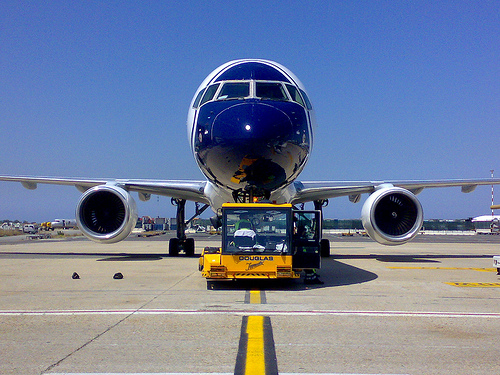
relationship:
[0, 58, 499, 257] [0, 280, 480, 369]
jet on tarmac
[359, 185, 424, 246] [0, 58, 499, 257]
engine on jet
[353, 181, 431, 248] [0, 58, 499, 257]
engine on jet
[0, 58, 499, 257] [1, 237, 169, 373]
jet on tarmac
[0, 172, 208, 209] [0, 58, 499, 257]
wing on jet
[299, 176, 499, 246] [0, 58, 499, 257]
wing on jet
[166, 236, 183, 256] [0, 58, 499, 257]
wheel on jet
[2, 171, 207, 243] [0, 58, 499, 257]
wing on jet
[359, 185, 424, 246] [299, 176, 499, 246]
engine on wing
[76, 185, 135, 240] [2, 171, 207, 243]
engine on wing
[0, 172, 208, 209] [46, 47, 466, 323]
wing on plane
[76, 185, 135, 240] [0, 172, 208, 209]
engine on wing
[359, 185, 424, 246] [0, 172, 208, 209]
engine on wing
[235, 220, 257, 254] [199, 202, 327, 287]
person on vehicle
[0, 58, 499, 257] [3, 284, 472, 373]
jet on tarmac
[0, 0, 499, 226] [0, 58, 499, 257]
sky above jet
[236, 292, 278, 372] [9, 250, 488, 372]
markings on a field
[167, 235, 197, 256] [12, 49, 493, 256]
rear-landing wheels of an airplane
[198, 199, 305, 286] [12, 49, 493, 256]
vehicle pulling an airplane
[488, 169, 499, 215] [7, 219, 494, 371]
radio antennae on an airplane field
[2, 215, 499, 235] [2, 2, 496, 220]
horizon connecting sky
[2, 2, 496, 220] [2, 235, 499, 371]
sky with an airplane field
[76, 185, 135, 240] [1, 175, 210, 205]
engine on wing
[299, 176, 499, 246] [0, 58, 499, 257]
wing of jet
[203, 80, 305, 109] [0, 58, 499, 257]
windshield on jet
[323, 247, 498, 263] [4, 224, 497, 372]
shadow on concrete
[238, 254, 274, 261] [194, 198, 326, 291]
name on vehicle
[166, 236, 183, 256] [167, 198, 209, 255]
wheel on landing gear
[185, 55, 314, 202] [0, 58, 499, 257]
front of a jet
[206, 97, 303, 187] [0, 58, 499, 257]
nose on jet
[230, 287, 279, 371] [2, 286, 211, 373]
stripe on concrete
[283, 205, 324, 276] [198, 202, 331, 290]
door on vehicle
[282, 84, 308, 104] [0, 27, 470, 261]
window on plane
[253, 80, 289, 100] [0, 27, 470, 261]
window on plane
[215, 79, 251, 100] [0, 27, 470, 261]
window on plane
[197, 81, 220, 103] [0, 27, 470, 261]
window on plane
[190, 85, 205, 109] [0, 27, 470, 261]
window on plane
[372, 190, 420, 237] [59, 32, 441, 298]
turbine on plane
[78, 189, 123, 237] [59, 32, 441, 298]
turbine on plane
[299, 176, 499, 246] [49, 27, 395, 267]
wing on plane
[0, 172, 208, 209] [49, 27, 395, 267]
wing on plane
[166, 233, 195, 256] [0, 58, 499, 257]
wheel on jet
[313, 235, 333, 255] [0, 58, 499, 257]
wheel on jet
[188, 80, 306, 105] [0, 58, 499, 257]
cockpit on jet